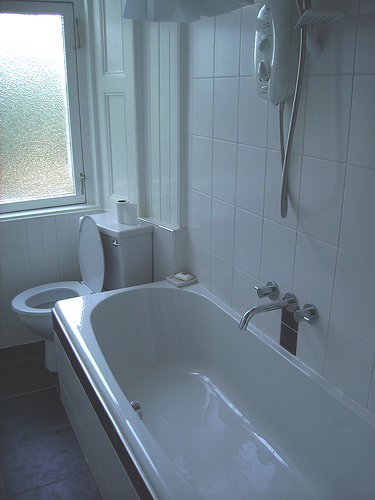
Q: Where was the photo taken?
A: It was taken at the bathroom.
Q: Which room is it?
A: It is a bathroom.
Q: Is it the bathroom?
A: Yes, it is the bathroom.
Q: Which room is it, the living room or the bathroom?
A: It is the bathroom.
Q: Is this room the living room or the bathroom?
A: It is the bathroom.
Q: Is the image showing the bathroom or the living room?
A: It is showing the bathroom.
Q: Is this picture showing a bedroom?
A: No, the picture is showing a bathroom.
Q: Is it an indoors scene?
A: Yes, it is indoors.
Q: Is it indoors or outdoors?
A: It is indoors.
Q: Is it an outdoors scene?
A: No, it is indoors.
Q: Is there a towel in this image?
A: No, there are no towels.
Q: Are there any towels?
A: No, there are no towels.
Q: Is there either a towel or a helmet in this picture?
A: No, there are no towels or helmets.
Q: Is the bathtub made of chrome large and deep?
A: Yes, the bathtub is large and deep.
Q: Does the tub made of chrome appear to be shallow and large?
A: No, the bathtub is large but deep.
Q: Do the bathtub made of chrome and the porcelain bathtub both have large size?
A: Yes, both the bathtub and the tub are large.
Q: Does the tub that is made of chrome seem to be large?
A: Yes, the bath tub is large.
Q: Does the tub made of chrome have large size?
A: Yes, the bath tub is large.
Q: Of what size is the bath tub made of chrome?
A: The bath tub is large.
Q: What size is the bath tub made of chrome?
A: The bath tub is large.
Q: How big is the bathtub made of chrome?
A: The bath tub is large.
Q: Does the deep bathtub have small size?
A: No, the bathtub is large.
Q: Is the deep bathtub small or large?
A: The tub is large.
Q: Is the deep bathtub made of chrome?
A: Yes, the bathtub is made of chrome.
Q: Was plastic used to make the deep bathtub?
A: No, the tub is made of chrome.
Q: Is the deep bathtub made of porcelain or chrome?
A: The bath tub is made of chrome.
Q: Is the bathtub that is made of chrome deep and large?
A: Yes, the bathtub is deep and large.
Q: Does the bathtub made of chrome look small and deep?
A: No, the bath tub is deep but large.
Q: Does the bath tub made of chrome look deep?
A: Yes, the bath tub is deep.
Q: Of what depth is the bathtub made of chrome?
A: The tub is deep.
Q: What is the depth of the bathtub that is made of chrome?
A: The tub is deep.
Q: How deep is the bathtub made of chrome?
A: The bathtub is deep.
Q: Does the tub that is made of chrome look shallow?
A: No, the bathtub is deep.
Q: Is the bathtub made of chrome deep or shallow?
A: The tub is deep.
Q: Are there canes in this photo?
A: No, there are no canes.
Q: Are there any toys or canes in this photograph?
A: No, there are no canes or toys.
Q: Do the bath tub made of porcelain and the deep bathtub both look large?
A: Yes, both the bath tub and the bathtub are large.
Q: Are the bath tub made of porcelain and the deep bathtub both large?
A: Yes, both the bath tub and the bathtub are large.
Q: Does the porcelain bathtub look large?
A: Yes, the bathtub is large.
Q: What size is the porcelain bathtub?
A: The bathtub is large.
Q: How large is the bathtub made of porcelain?
A: The tub is large.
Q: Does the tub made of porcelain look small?
A: No, the bathtub is large.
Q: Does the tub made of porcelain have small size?
A: No, the bathtub is large.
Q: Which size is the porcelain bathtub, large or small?
A: The bathtub is large.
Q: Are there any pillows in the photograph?
A: No, there are no pillows.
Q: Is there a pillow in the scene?
A: No, there are no pillows.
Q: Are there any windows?
A: Yes, there is a window.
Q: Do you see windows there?
A: Yes, there is a window.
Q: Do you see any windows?
A: Yes, there is a window.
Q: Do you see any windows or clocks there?
A: Yes, there is a window.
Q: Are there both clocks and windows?
A: No, there is a window but no clocks.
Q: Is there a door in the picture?
A: No, there are no doors.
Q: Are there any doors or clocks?
A: No, there are no doors or clocks.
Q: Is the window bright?
A: Yes, the window is bright.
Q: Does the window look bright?
A: Yes, the window is bright.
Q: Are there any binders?
A: No, there are no binders.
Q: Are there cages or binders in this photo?
A: No, there are no binders or cages.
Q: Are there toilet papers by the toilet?
A: Yes, there is a toilet paper by the toilet.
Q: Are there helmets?
A: No, there are no helmets.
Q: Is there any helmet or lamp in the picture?
A: No, there are no helmets or lamps.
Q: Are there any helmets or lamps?
A: No, there are no helmets or lamps.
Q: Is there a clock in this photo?
A: No, there are no clocks.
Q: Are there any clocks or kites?
A: No, there are no clocks or kites.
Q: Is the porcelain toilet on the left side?
A: Yes, the toilet is on the left of the image.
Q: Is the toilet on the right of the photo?
A: No, the toilet is on the left of the image.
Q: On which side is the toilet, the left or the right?
A: The toilet is on the left of the image.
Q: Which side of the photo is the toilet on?
A: The toilet is on the left of the image.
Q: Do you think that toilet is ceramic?
A: Yes, the toilet is ceramic.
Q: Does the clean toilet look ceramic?
A: Yes, the toilet is ceramic.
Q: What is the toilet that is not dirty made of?
A: The toilet is made of porcelain.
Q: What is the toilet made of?
A: The toilet is made of porcelain.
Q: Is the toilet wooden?
A: No, the toilet is ceramic.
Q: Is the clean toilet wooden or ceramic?
A: The toilet is ceramic.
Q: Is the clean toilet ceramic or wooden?
A: The toilet is ceramic.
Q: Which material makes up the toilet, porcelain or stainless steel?
A: The toilet is made of porcelain.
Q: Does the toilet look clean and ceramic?
A: Yes, the toilet is clean and ceramic.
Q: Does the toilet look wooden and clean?
A: No, the toilet is clean but ceramic.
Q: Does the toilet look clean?
A: Yes, the toilet is clean.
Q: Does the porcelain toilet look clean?
A: Yes, the toilet is clean.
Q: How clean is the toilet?
A: The toilet is clean.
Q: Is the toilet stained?
A: No, the toilet is clean.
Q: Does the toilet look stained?
A: No, the toilet is clean.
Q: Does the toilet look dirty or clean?
A: The toilet is clean.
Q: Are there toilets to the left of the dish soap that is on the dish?
A: Yes, there is a toilet to the left of the dish soap.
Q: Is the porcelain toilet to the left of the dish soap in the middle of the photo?
A: Yes, the toilet is to the left of the dish soap.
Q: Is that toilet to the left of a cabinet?
A: No, the toilet is to the left of the dish soap.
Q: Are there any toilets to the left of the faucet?
A: Yes, there is a toilet to the left of the faucet.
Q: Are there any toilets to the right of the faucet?
A: No, the toilet is to the left of the faucet.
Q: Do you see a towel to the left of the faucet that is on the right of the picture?
A: No, there is a toilet to the left of the tap.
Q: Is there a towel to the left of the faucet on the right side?
A: No, there is a toilet to the left of the tap.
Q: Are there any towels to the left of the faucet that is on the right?
A: No, there is a toilet to the left of the tap.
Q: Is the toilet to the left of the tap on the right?
A: Yes, the toilet is to the left of the tap.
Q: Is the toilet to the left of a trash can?
A: No, the toilet is to the left of the tap.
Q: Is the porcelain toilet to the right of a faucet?
A: No, the toilet is to the left of a faucet.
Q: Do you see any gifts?
A: No, there are no gifts.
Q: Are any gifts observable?
A: No, there are no gifts.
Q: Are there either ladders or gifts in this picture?
A: No, there are no gifts or ladders.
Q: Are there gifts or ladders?
A: No, there are no gifts or ladders.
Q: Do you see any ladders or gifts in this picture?
A: No, there are no gifts or ladders.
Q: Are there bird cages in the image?
A: No, there are no bird cages.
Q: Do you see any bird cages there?
A: No, there are no bird cages.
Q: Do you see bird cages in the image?
A: No, there are no bird cages.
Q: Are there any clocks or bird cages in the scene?
A: No, there are no bird cages or clocks.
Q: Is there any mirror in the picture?
A: No, there are no mirrors.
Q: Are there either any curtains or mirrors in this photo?
A: No, there are no mirrors or curtains.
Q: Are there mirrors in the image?
A: No, there are no mirrors.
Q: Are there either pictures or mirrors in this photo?
A: No, there are no mirrors or pictures.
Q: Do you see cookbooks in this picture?
A: No, there are no cookbooks.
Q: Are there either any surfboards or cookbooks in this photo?
A: No, there are no cookbooks or surfboards.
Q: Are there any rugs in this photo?
A: No, there are no rugs.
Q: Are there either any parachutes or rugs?
A: No, there are no rugs or parachutes.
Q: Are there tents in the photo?
A: No, there are no tents.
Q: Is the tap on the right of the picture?
A: Yes, the tap is on the right of the image.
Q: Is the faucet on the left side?
A: No, the faucet is on the right of the image.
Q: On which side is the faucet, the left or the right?
A: The faucet is on the right of the image.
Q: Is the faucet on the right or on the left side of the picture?
A: The faucet is on the right of the image.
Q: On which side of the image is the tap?
A: The tap is on the right of the image.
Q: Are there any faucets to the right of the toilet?
A: Yes, there is a faucet to the right of the toilet.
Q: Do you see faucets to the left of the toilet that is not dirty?
A: No, the faucet is to the right of the toilet.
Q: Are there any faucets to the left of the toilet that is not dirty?
A: No, the faucet is to the right of the toilet.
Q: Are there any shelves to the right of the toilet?
A: No, there is a faucet to the right of the toilet.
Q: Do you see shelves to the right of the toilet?
A: No, there is a faucet to the right of the toilet.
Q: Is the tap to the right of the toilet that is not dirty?
A: Yes, the tap is to the right of the toilet.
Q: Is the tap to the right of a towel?
A: No, the tap is to the right of the toilet.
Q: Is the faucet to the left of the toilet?
A: No, the faucet is to the right of the toilet.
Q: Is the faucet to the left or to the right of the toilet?
A: The faucet is to the right of the toilet.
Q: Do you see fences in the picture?
A: No, there are no fences.